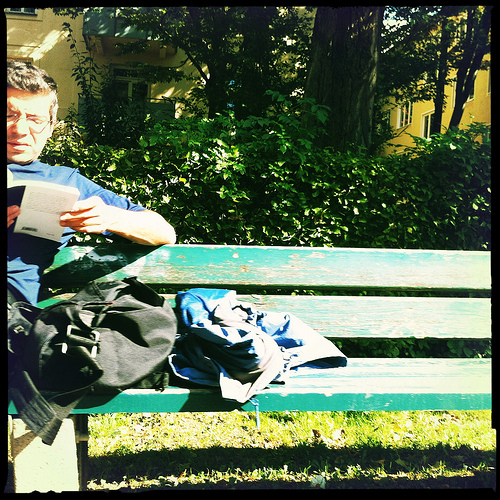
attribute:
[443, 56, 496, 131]
paint — yellow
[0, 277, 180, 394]
bag — green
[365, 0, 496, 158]
house — yellow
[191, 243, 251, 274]
paint — chipped